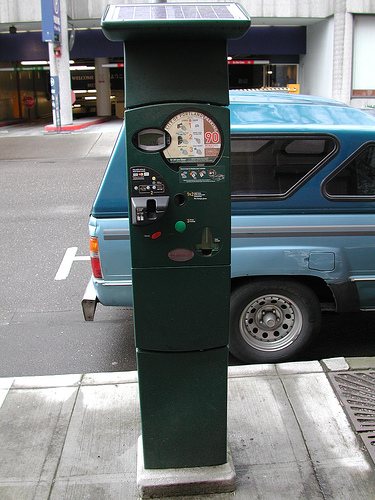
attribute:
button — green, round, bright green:
[172, 218, 186, 233]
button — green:
[172, 218, 190, 235]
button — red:
[146, 227, 164, 243]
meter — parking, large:
[95, 6, 254, 464]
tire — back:
[224, 282, 312, 362]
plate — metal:
[330, 351, 362, 473]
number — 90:
[203, 126, 222, 150]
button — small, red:
[148, 227, 162, 246]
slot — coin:
[198, 223, 212, 250]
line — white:
[51, 239, 85, 284]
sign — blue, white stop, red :
[36, 4, 61, 41]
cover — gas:
[306, 247, 338, 273]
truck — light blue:
[83, 218, 345, 344]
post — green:
[96, 4, 252, 464]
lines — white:
[52, 246, 88, 280]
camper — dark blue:
[92, 93, 374, 216]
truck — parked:
[79, 91, 374, 366]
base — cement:
[135, 431, 235, 498]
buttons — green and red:
[149, 220, 187, 239]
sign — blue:
[40, 1, 60, 41]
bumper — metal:
[79, 273, 96, 321]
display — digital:
[133, 128, 171, 153]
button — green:
[174, 220, 184, 232]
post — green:
[122, 42, 228, 469]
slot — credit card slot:
[137, 206, 162, 212]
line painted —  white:
[59, 242, 79, 285]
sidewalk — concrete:
[11, 412, 98, 498]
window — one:
[28, 65, 62, 126]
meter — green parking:
[105, 8, 248, 495]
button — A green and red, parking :
[150, 212, 193, 246]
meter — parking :
[99, 38, 255, 496]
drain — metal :
[326, 357, 361, 441]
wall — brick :
[305, 30, 339, 94]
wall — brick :
[334, 16, 341, 101]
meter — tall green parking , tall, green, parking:
[96, 3, 271, 489]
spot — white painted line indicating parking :
[45, 248, 73, 287]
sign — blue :
[39, 6, 62, 49]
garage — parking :
[5, 18, 334, 109]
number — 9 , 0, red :
[204, 119, 228, 155]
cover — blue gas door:
[306, 249, 340, 275]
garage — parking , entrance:
[9, 27, 308, 111]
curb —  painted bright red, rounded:
[20, 362, 93, 382]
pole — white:
[39, 29, 72, 125]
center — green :
[44, 8, 65, 126]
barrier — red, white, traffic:
[224, 80, 305, 94]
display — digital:
[132, 128, 166, 149]